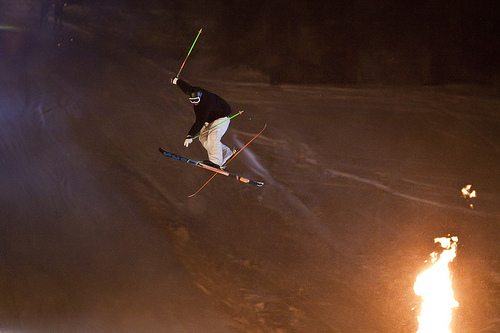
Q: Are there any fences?
A: No, there are no fences.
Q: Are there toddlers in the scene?
A: No, there are no toddlers.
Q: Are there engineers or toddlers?
A: No, there are no toddlers or engineers.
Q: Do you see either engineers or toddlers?
A: No, there are no toddlers or engineers.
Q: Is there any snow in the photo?
A: Yes, there is snow.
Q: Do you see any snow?
A: Yes, there is snow.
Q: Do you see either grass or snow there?
A: Yes, there is snow.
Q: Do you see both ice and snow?
A: No, there is snow but no ice.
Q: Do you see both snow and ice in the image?
A: No, there is snow but no ice.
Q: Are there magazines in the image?
A: No, there are no magazines.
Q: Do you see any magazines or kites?
A: No, there are no magazines or kites.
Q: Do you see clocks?
A: No, there are no clocks.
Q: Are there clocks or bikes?
A: No, there are no clocks or bikes.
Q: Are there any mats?
A: No, there are no mats.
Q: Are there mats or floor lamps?
A: No, there are no mats or floor lamps.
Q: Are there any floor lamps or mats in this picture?
A: No, there are no mats or floor lamps.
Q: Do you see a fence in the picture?
A: No, there are no fences.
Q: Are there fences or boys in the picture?
A: No, there are no fences or boys.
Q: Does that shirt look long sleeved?
A: Yes, the shirt is long sleeved.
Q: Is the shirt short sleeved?
A: No, the shirt is long sleeved.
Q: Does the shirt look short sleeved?
A: No, the shirt is long sleeved.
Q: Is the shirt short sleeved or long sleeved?
A: The shirt is long sleeved.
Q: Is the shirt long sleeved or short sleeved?
A: The shirt is long sleeved.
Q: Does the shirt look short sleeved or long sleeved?
A: The shirt is long sleeved.